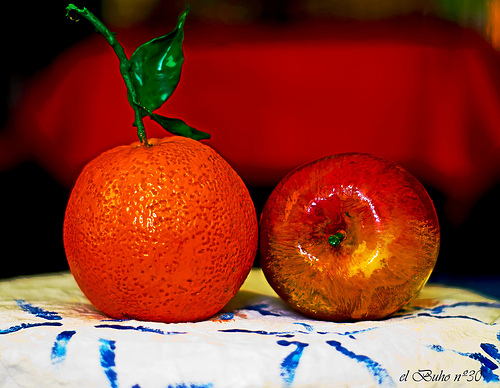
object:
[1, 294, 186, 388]
design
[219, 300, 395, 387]
design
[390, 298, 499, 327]
design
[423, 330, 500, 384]
design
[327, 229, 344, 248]
stem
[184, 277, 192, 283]
dimple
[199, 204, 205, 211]
dimple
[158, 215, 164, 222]
dimple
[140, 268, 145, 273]
dimple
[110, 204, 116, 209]
dimple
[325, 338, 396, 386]
line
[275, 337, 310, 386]
line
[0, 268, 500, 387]
cloth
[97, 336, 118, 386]
line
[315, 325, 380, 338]
line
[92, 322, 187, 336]
line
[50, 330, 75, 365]
line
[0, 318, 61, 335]
line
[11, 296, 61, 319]
line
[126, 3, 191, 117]
leaf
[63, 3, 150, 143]
stem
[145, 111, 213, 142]
leaf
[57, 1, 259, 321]
orange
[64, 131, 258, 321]
orange peel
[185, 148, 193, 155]
pore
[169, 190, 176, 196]
pore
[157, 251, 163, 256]
pore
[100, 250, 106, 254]
pore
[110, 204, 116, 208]
pore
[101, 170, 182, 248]
light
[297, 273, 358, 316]
part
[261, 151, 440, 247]
part red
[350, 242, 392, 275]
part yellow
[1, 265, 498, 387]
table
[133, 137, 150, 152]
top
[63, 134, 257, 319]
circle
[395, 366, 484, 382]
logo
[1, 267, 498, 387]
surface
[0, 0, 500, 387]
background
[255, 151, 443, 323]
apple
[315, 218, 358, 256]
top